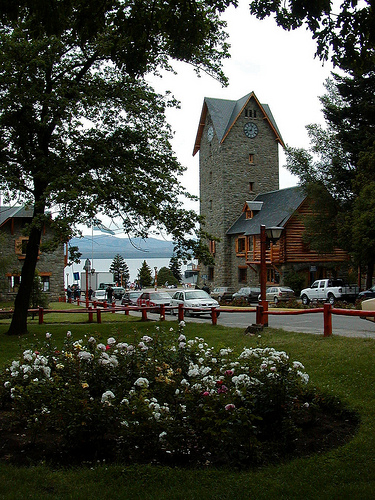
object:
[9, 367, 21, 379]
flowers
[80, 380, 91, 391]
yellow flowers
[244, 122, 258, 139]
clock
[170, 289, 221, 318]
car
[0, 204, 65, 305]
building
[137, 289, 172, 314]
car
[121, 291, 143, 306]
car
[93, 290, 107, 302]
car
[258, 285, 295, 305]
car